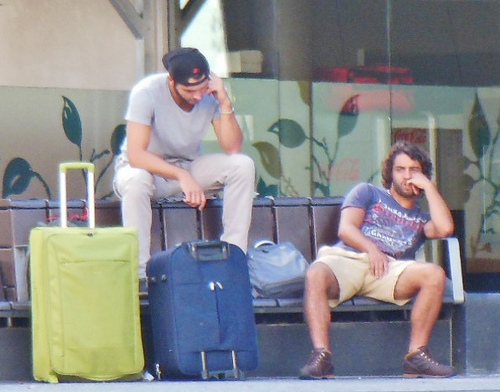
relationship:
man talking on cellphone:
[111, 47, 256, 291] [207, 70, 212, 84]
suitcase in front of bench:
[27, 160, 144, 384] [153, 155, 453, 327]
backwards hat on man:
[156, 45, 218, 88] [111, 47, 256, 291]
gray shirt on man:
[113, 71, 222, 199] [122, 47, 268, 245]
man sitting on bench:
[299, 140, 458, 380] [0, 192, 468, 377]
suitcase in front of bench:
[27, 225, 146, 382] [0, 192, 468, 377]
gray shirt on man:
[349, 178, 426, 268] [299, 140, 458, 380]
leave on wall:
[61, 93, 86, 148] [4, 65, 499, 259]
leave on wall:
[0, 156, 41, 201] [4, 65, 499, 259]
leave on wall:
[270, 119, 305, 144] [4, 65, 499, 259]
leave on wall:
[107, 121, 125, 153] [4, 65, 499, 259]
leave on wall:
[252, 139, 284, 179] [4, 65, 499, 259]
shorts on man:
[313, 240, 413, 306] [260, 141, 463, 358]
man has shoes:
[299, 140, 458, 380] [289, 334, 461, 390]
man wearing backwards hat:
[107, 45, 264, 286] [158, 46, 211, 88]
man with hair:
[299, 140, 458, 380] [374, 137, 438, 191]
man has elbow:
[346, 167, 461, 380] [427, 205, 467, 245]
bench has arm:
[0, 192, 468, 377] [436, 237, 466, 306]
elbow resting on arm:
[427, 205, 467, 245] [436, 237, 466, 306]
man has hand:
[299, 140, 458, 380] [404, 169, 460, 240]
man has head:
[299, 140, 458, 380] [380, 139, 431, 196]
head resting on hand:
[380, 139, 431, 196] [404, 169, 460, 240]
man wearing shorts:
[299, 140, 458, 380] [313, 240, 413, 306]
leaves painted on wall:
[269, 90, 359, 198] [3, 1, 499, 292]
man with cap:
[111, 47, 256, 291] [157, 43, 210, 86]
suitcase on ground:
[153, 238, 257, 380] [10, 367, 498, 389]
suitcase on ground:
[27, 160, 144, 384] [10, 367, 498, 389]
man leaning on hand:
[299, 140, 458, 380] [405, 171, 430, 194]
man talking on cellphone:
[107, 45, 264, 286] [207, 70, 214, 80]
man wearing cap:
[111, 47, 256, 291] [159, 40, 211, 95]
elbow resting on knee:
[120, 145, 151, 169] [117, 162, 155, 199]